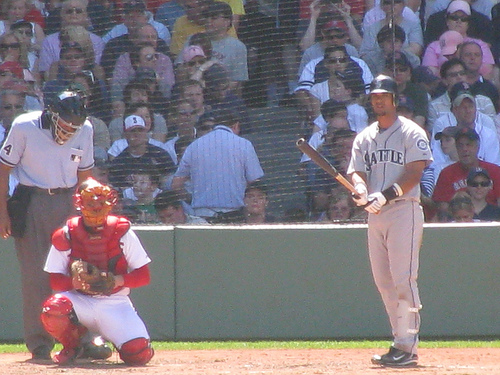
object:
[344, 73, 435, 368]
batter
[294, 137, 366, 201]
bat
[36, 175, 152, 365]
catcher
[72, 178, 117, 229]
facemask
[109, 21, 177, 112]
people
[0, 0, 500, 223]
net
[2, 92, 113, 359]
umpire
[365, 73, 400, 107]
helmet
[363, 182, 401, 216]
glove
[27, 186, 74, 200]
belt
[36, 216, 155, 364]
uniform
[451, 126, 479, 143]
hat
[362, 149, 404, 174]
writing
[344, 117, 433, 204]
jersey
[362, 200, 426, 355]
pants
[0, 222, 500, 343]
wall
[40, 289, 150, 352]
pants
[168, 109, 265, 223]
man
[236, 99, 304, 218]
stairs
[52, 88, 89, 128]
helmet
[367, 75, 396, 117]
head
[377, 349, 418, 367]
shoes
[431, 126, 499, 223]
man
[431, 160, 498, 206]
shirt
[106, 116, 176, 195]
man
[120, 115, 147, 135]
hat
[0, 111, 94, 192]
shirt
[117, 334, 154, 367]
knee pad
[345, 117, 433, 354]
uniform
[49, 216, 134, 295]
protective gear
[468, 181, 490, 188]
sunglasses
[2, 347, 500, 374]
dirt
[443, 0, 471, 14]
hat